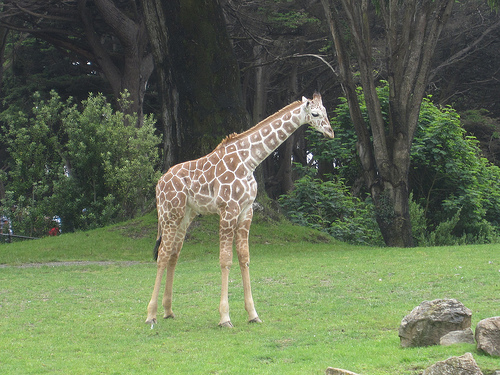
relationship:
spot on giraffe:
[207, 160, 247, 193] [108, 75, 330, 345]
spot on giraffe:
[169, 194, 183, 208] [138, 79, 341, 316]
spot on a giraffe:
[256, 121, 275, 138] [143, 90, 336, 332]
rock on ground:
[397, 298, 472, 350] [299, 268, 471, 373]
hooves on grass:
[218, 320, 261, 327] [343, 257, 484, 298]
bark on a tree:
[366, 150, 421, 251] [216, 0, 498, 247]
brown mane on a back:
[212, 129, 237, 146] [158, 134, 234, 184]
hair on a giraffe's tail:
[153, 236, 163, 263] [151, 217, 163, 263]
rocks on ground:
[342, 294, 496, 366] [297, 302, 462, 372]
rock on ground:
[474, 315, 496, 358] [0, 187, 499, 370]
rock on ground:
[399, 297, 473, 350] [0, 187, 499, 370]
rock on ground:
[405, 350, 486, 374] [0, 187, 499, 370]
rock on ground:
[327, 364, 357, 374] [0, 187, 499, 370]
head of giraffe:
[299, 90, 336, 137] [143, 90, 336, 332]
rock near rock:
[399, 297, 473, 350] [474, 315, 499, 355]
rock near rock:
[399, 297, 473, 350] [422, 352, 482, 374]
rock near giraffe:
[399, 297, 473, 350] [143, 90, 336, 332]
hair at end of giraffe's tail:
[148, 238, 161, 258] [149, 180, 168, 264]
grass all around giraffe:
[0, 202, 498, 374] [143, 90, 336, 332]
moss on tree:
[175, 3, 243, 218] [149, 10, 242, 153]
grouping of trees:
[282, 1, 499, 238] [255, 0, 498, 245]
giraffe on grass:
[143, 90, 336, 332] [0, 206, 500, 375]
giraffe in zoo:
[143, 90, 336, 332] [0, 0, 500, 375]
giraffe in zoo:
[143, 90, 336, 332] [2, 0, 493, 374]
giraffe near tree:
[143, 90, 336, 332] [330, 1, 453, 247]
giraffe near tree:
[143, 90, 336, 332] [55, 5, 240, 140]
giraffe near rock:
[143, 49, 336, 355] [395, 288, 477, 350]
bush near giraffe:
[3, 84, 164, 264] [143, 90, 336, 332]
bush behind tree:
[301, 78, 498, 237] [337, 67, 439, 229]